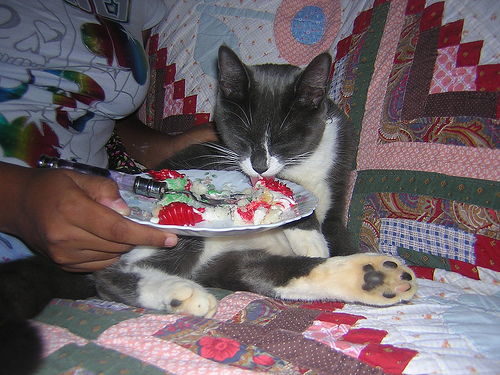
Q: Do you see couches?
A: Yes, there is a couch.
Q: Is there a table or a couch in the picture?
A: Yes, there is a couch.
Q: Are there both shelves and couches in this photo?
A: No, there is a couch but no shelves.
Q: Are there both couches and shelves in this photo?
A: No, there is a couch but no shelves.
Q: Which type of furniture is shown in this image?
A: The furniture is a couch.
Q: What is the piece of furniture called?
A: The piece of furniture is a couch.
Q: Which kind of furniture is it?
A: The piece of furniture is a couch.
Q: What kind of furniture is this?
A: This is a couch.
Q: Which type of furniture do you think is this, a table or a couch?
A: This is a couch.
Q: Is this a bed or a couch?
A: This is a couch.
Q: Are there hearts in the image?
A: Yes, there is a heart.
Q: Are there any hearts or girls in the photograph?
A: Yes, there is a heart.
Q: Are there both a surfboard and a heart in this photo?
A: No, there is a heart but no surfboards.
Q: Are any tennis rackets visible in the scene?
A: No, there are no tennis rackets.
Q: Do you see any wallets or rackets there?
A: No, there are no rackets or wallets.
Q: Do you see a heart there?
A: Yes, there is a heart.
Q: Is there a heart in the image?
A: Yes, there is a heart.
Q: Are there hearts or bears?
A: Yes, there is a heart.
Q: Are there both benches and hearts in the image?
A: No, there is a heart but no benches.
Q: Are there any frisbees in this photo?
A: No, there are no frisbees.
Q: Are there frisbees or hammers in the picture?
A: No, there are no frisbees or hammers.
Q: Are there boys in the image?
A: No, there are no boys.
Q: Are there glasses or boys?
A: No, there are no boys or glasses.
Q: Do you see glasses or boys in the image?
A: No, there are no boys or glasses.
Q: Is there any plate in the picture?
A: Yes, there is a plate.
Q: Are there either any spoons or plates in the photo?
A: Yes, there is a plate.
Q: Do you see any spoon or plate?
A: Yes, there is a plate.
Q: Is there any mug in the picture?
A: No, there are no mugs.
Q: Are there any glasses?
A: No, there are no glasses.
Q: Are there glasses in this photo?
A: No, there are no glasses.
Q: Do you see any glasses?
A: No, there are no glasses.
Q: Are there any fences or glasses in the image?
A: No, there are no glasses or fences.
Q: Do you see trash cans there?
A: No, there are no trash cans.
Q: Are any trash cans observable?
A: No, there are no trash cans.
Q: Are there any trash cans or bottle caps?
A: No, there are no trash cans or bottle caps.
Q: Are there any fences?
A: No, there are no fences.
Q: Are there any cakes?
A: Yes, there is a cake.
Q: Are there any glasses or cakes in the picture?
A: Yes, there is a cake.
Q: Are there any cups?
A: No, there are no cups.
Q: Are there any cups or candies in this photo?
A: No, there are no cups or candies.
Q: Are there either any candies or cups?
A: No, there are no cups or candies.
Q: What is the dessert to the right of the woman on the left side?
A: The dessert is a cake.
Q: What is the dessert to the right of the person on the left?
A: The dessert is a cake.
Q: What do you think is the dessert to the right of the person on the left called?
A: The dessert is a cake.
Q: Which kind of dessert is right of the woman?
A: The dessert is a cake.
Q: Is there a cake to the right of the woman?
A: Yes, there is a cake to the right of the woman.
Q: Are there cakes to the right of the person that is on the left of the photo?
A: Yes, there is a cake to the right of the woman.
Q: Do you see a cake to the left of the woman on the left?
A: No, the cake is to the right of the woman.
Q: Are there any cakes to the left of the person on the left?
A: No, the cake is to the right of the woman.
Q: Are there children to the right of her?
A: No, there is a cake to the right of the woman.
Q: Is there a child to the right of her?
A: No, there is a cake to the right of the woman.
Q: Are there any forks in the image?
A: Yes, there is a fork.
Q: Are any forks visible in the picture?
A: Yes, there is a fork.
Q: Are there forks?
A: Yes, there is a fork.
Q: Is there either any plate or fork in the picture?
A: Yes, there is a fork.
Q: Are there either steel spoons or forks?
A: Yes, there is a steel fork.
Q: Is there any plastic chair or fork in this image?
A: Yes, there is a plastic fork.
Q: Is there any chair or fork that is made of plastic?
A: Yes, the fork is made of plastic.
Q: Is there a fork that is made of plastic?
A: Yes, there is a fork that is made of plastic.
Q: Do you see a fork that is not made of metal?
A: Yes, there is a fork that is made of plastic.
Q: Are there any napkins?
A: No, there are no napkins.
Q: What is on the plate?
A: The fork is on the plate.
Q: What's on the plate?
A: The fork is on the plate.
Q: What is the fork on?
A: The fork is on the plate.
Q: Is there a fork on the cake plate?
A: Yes, there is a fork on the plate.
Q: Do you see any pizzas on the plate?
A: No, there is a fork on the plate.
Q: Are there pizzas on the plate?
A: No, there is a fork on the plate.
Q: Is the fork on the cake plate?
A: Yes, the fork is on the plate.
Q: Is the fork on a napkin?
A: No, the fork is on the plate.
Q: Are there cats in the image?
A: Yes, there is a cat.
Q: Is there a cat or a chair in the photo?
A: Yes, there is a cat.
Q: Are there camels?
A: No, there are no camels.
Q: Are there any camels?
A: No, there are no camels.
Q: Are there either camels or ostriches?
A: No, there are no camels or ostriches.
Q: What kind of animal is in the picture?
A: The animal is a cat.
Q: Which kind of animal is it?
A: The animal is a cat.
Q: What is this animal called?
A: That is a cat.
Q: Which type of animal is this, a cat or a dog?
A: That is a cat.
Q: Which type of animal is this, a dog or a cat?
A: That is a cat.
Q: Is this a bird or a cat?
A: This is a cat.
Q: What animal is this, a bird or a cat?
A: This is a cat.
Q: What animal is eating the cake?
A: The cat is eating the cake.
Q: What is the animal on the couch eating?
A: The cat is eating a cake.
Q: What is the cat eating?
A: The cat is eating a cake.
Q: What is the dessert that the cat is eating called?
A: The dessert is a cake.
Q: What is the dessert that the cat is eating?
A: The dessert is a cake.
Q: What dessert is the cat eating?
A: The cat is eating a cake.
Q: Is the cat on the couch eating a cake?
A: Yes, the cat is eating a cake.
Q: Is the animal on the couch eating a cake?
A: Yes, the cat is eating a cake.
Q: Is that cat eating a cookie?
A: No, the cat is eating a cake.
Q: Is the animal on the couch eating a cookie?
A: No, the cat is eating a cake.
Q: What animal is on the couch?
A: The cat is on the couch.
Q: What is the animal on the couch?
A: The animal is a cat.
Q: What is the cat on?
A: The cat is on the couch.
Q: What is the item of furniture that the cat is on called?
A: The piece of furniture is a couch.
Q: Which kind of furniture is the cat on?
A: The cat is on the couch.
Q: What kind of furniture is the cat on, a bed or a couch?
A: The cat is on a couch.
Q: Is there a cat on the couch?
A: Yes, there is a cat on the couch.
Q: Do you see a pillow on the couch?
A: No, there is a cat on the couch.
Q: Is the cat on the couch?
A: Yes, the cat is on the couch.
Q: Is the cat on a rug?
A: No, the cat is on the couch.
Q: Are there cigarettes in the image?
A: No, there are no cigarettes.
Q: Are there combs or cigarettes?
A: No, there are no cigarettes or combs.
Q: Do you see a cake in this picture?
A: Yes, there is a cake.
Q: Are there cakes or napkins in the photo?
A: Yes, there is a cake.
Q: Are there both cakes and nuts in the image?
A: No, there is a cake but no nuts.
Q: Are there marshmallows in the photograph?
A: No, there are no marshmallows.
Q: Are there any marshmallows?
A: No, there are no marshmallows.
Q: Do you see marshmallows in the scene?
A: No, there are no marshmallows.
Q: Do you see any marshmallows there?
A: No, there are no marshmallows.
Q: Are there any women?
A: Yes, there is a woman.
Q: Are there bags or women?
A: Yes, there is a woman.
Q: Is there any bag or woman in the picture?
A: Yes, there is a woman.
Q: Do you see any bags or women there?
A: Yes, there is a woman.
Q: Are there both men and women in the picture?
A: No, there is a woman but no men.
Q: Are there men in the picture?
A: No, there are no men.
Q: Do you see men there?
A: No, there are no men.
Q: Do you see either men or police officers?
A: No, there are no men or police officers.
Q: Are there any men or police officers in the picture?
A: No, there are no men or police officers.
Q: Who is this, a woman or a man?
A: This is a woman.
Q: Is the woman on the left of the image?
A: Yes, the woman is on the left of the image.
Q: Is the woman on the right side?
A: No, the woman is on the left of the image.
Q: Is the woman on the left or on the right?
A: The woman is on the left of the image.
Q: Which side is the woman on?
A: The woman is on the left of the image.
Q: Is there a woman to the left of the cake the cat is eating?
A: Yes, there is a woman to the left of the cake.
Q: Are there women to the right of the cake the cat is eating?
A: No, the woman is to the left of the cake.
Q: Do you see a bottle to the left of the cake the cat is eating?
A: No, there is a woman to the left of the cake.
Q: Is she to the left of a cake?
A: Yes, the woman is to the left of a cake.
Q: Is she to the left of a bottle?
A: No, the woman is to the left of a cake.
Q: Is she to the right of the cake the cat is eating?
A: No, the woman is to the left of the cake.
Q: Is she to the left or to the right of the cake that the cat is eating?
A: The woman is to the left of the cake.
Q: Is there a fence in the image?
A: No, there are no fences.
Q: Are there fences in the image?
A: No, there are no fences.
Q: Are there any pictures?
A: No, there are no pictures.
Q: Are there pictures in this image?
A: No, there are no pictures.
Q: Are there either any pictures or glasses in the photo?
A: No, there are no pictures or glasses.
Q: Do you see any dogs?
A: No, there are no dogs.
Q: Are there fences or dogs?
A: No, there are no dogs or fences.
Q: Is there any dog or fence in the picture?
A: No, there are no dogs or fences.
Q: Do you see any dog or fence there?
A: No, there are no dogs or fences.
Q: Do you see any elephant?
A: No, there are no elephants.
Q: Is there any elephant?
A: No, there are no elephants.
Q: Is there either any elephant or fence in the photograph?
A: No, there are no elephants or fences.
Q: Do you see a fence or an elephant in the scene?
A: No, there are no elephants or fences.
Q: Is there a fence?
A: No, there are no fences.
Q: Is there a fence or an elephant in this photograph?
A: No, there are no fences or elephants.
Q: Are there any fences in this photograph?
A: No, there are no fences.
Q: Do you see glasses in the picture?
A: No, there are no glasses.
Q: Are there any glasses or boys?
A: No, there are no glasses or boys.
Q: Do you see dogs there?
A: No, there are no dogs.